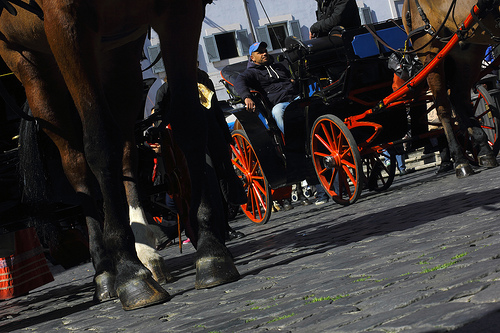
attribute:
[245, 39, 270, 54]
cap — blue, ball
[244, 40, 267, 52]
hat — blue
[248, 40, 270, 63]
head — man's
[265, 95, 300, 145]
jeans — blue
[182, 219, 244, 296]
hoof — large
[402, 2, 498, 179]
horse — brown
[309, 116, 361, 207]
wheel — black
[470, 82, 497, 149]
wheel — black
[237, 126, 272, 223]
wheel — black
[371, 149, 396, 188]
wheel — black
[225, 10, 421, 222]
carriage — orange, black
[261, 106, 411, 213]
wheel — red, wooden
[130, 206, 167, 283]
hoof — white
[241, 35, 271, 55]
cap — blue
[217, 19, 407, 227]
blue wagon — black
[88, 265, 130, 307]
hoof — black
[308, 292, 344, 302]
grass — brick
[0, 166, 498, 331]
brick pavement — grey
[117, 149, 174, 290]
leg — white, horse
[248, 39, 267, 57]
cap — baseball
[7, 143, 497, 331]
pavement — brick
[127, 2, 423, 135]
building — grey